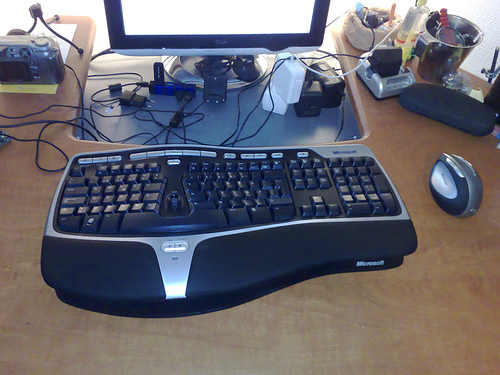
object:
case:
[400, 77, 498, 137]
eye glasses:
[398, 82, 500, 136]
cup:
[416, 15, 484, 83]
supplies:
[439, 8, 454, 43]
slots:
[187, 84, 197, 96]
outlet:
[201, 77, 230, 104]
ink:
[395, 6, 423, 69]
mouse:
[426, 152, 484, 218]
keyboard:
[51, 148, 398, 233]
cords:
[226, 57, 287, 147]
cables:
[0, 121, 81, 172]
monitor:
[122, 0, 316, 36]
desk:
[0, 21, 499, 374]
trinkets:
[436, 25, 468, 45]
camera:
[0, 37, 68, 85]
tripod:
[23, 4, 83, 55]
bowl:
[345, 8, 403, 52]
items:
[388, 2, 397, 25]